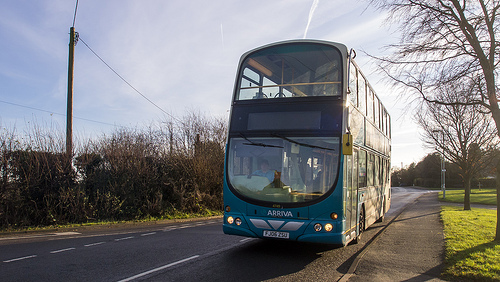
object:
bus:
[220, 39, 392, 248]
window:
[226, 136, 342, 209]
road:
[0, 185, 443, 282]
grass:
[440, 208, 499, 281]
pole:
[66, 27, 75, 164]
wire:
[71, 0, 80, 27]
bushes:
[0, 108, 228, 228]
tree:
[357, 0, 499, 139]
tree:
[410, 79, 499, 210]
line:
[117, 255, 201, 281]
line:
[82, 241, 104, 249]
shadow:
[366, 224, 386, 229]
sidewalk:
[340, 191, 441, 281]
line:
[301, 0, 317, 39]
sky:
[0, 0, 499, 182]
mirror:
[342, 134, 352, 156]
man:
[250, 160, 275, 181]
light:
[322, 222, 334, 231]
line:
[75, 33, 197, 131]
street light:
[439, 129, 446, 199]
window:
[233, 42, 343, 102]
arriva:
[266, 210, 293, 217]